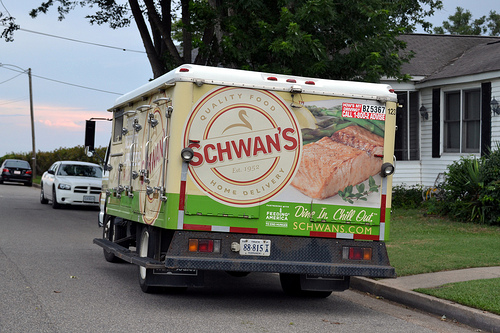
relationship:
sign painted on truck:
[105, 82, 395, 239] [85, 64, 403, 299]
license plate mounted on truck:
[238, 238, 270, 256] [85, 64, 403, 299]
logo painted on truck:
[183, 86, 303, 209] [85, 64, 403, 299]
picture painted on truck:
[289, 104, 386, 205] [85, 64, 403, 299]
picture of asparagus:
[289, 104, 386, 205] [300, 106, 384, 146]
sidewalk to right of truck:
[376, 267, 500, 291] [85, 64, 403, 299]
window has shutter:
[443, 86, 481, 154] [430, 87, 442, 158]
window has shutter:
[443, 86, 481, 154] [480, 82, 491, 160]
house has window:
[342, 31, 499, 199] [443, 86, 481, 154]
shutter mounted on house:
[430, 87, 442, 158] [342, 31, 499, 199]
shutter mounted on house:
[480, 82, 491, 160] [342, 31, 499, 199]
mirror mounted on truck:
[83, 120, 96, 157] [85, 64, 403, 299]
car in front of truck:
[39, 160, 104, 209] [85, 64, 403, 299]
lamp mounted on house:
[417, 102, 428, 123] [342, 31, 499, 199]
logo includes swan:
[183, 86, 303, 209] [221, 109, 254, 134]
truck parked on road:
[85, 64, 403, 299] [1, 179, 489, 332]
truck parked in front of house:
[85, 64, 403, 299] [342, 31, 499, 199]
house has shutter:
[342, 31, 499, 199] [430, 87, 442, 158]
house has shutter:
[342, 31, 499, 199] [480, 82, 491, 160]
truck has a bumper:
[85, 64, 403, 299] [164, 231, 396, 278]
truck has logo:
[85, 64, 403, 299] [183, 86, 303, 209]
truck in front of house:
[85, 64, 403, 299] [342, 31, 499, 199]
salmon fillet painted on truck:
[290, 125, 384, 200] [85, 64, 403, 299]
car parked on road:
[39, 160, 104, 209] [1, 179, 489, 332]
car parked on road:
[1, 157, 34, 185] [1, 179, 489, 332]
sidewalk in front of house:
[376, 267, 500, 291] [342, 31, 499, 199]